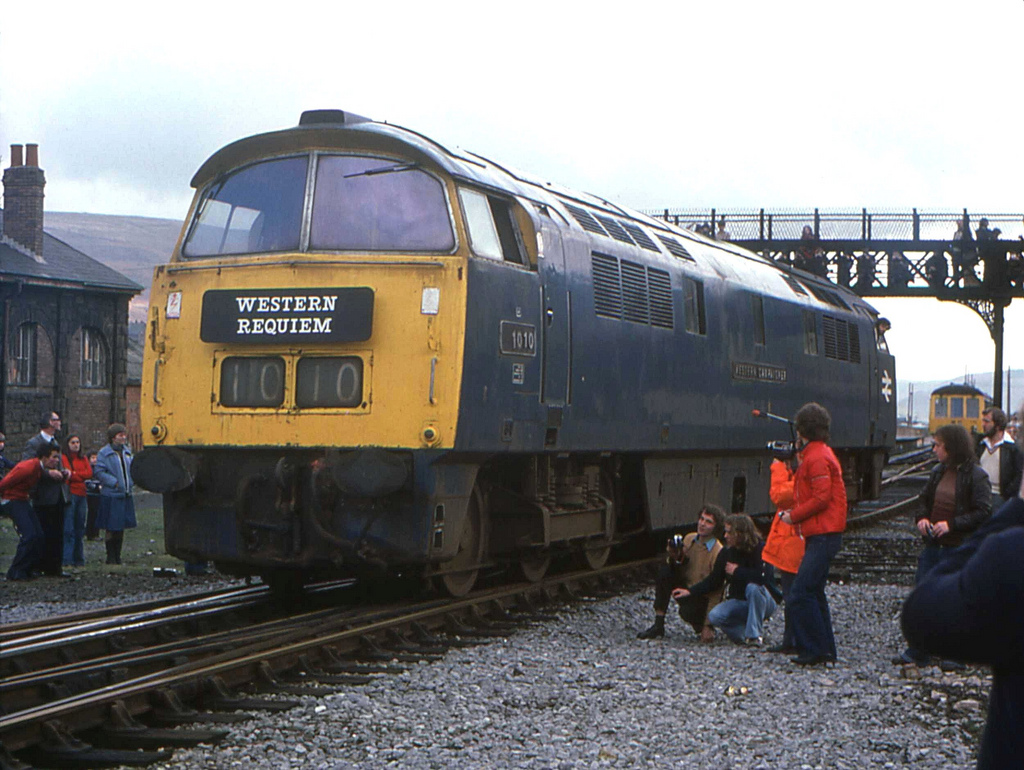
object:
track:
[0, 537, 685, 769]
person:
[641, 503, 723, 637]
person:
[671, 508, 783, 645]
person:
[93, 421, 139, 566]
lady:
[892, 422, 991, 668]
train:
[132, 108, 899, 598]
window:
[82, 326, 114, 386]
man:
[0, 443, 65, 584]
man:
[974, 405, 1024, 512]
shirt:
[977, 434, 1010, 494]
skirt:
[96, 495, 142, 531]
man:
[636, 501, 721, 640]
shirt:
[926, 466, 959, 543]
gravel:
[137, 498, 988, 770]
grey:
[458, 633, 581, 770]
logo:
[232, 293, 338, 337]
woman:
[889, 422, 991, 668]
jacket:
[918, 463, 994, 548]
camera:
[925, 521, 941, 539]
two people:
[632, 505, 782, 652]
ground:
[148, 567, 996, 770]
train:
[929, 381, 1001, 435]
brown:
[0, 611, 189, 769]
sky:
[0, 0, 1022, 216]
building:
[0, 140, 147, 463]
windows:
[2, 319, 38, 387]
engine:
[544, 230, 665, 450]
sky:
[0, 0, 1022, 212]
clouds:
[315, 0, 651, 115]